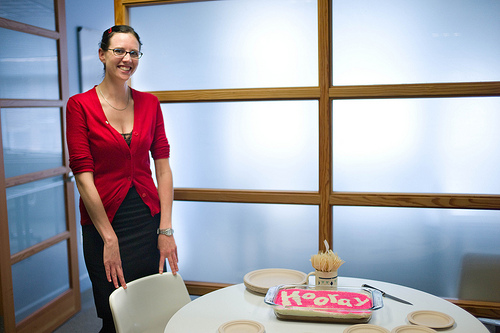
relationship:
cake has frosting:
[274, 286, 375, 323] [274, 287, 373, 313]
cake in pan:
[274, 286, 375, 323] [264, 283, 384, 324]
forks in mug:
[308, 237, 346, 271] [305, 269, 340, 288]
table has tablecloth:
[164, 274, 495, 332] [160, 276, 493, 332]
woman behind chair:
[66, 24, 181, 332] [109, 269, 195, 331]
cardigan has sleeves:
[65, 84, 172, 228] [65, 95, 171, 175]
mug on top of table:
[305, 269, 340, 288] [164, 274, 495, 332]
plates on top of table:
[244, 267, 308, 293] [164, 274, 495, 332]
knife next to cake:
[361, 280, 416, 307] [274, 286, 375, 323]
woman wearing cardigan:
[66, 24, 181, 332] [65, 84, 172, 228]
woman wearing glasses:
[66, 24, 181, 332] [102, 46, 144, 60]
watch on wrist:
[155, 226, 177, 236] [156, 223, 177, 240]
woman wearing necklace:
[66, 24, 181, 332] [97, 82, 135, 112]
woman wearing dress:
[66, 24, 181, 332] [83, 184, 173, 320]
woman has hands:
[66, 24, 181, 332] [102, 233, 181, 289]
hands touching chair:
[102, 233, 181, 289] [109, 269, 195, 331]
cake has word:
[274, 286, 375, 323] [280, 288, 370, 310]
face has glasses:
[102, 32, 141, 81] [102, 46, 144, 60]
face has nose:
[102, 32, 141, 81] [122, 52, 135, 65]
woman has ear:
[66, 24, 181, 332] [96, 46, 109, 64]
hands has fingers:
[102, 233, 181, 289] [103, 249, 181, 288]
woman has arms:
[66, 24, 181, 332] [65, 100, 181, 288]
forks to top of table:
[308, 237, 346, 271] [164, 274, 495, 332]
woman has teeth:
[66, 24, 181, 332] [117, 63, 133, 72]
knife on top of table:
[361, 280, 416, 307] [164, 274, 495, 332]